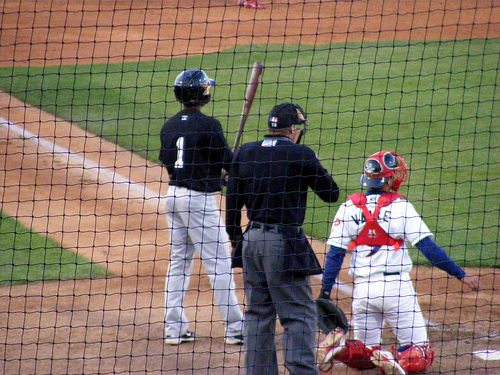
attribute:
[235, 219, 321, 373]
pants — gray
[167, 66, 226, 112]
helmet — black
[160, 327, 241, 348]
shoes — black, white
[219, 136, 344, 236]
shirt — black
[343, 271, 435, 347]
pants — white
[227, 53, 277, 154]
bat — wooden, baseball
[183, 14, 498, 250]
baseball court — green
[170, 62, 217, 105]
helmet — black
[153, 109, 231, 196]
shirt — black, white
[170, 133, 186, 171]
number — white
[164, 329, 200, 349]
shoe — black, white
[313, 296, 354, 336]
glove — black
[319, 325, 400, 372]
shoes — white , red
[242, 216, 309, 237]
belt — black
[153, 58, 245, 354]
person — playing baseball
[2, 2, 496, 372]
baseball court — brown, green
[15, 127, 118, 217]
baseball court — brown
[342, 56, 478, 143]
baseball court — green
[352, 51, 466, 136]
baseball court — green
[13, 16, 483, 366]
netting — black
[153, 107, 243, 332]
uniform — black, white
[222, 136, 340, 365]
outfit — dark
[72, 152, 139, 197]
dirt — brown, white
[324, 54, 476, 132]
grass — green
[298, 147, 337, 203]
sleeve — black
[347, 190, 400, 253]
straps — red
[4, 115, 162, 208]
line — white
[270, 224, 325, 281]
pouch — black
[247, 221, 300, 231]
belt — black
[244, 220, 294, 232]
loops — gray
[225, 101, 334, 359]
person — making the official calls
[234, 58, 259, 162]
baseball bat — dark brown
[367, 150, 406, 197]
helmet — red, blue, protective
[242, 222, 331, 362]
pair — grey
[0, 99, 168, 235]
line — white, foul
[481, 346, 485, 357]
plate — baseball, home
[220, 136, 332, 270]
shirt — dark blue, long sleeve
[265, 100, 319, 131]
cap — black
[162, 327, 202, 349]
shoe — blue, white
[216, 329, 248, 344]
shoe — white, blue, athletic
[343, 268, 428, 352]
pants — white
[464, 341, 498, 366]
plate — white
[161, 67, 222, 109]
helmet — black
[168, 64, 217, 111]
helmet — black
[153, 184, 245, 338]
pants — white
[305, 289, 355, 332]
glove — black